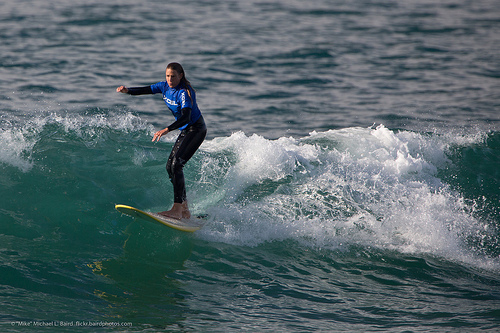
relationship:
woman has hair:
[109, 69, 225, 220] [126, 72, 225, 112]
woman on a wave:
[109, 69, 225, 220] [4, 112, 483, 236]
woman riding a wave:
[109, 69, 225, 220] [4, 112, 483, 236]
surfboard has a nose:
[90, 192, 246, 239] [108, 195, 156, 214]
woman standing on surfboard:
[109, 69, 225, 220] [90, 192, 246, 239]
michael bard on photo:
[28, 318, 115, 331] [33, 10, 475, 319]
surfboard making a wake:
[90, 192, 246, 239] [190, 172, 388, 264]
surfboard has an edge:
[90, 192, 246, 239] [148, 219, 203, 235]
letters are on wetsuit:
[153, 93, 188, 104] [126, 82, 228, 212]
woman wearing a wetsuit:
[109, 69, 225, 220] [126, 82, 228, 212]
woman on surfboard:
[109, 69, 225, 220] [90, 192, 246, 239]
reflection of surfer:
[82, 217, 194, 328] [117, 61, 206, 218]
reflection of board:
[82, 217, 194, 328] [114, 203, 212, 233]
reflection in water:
[82, 217, 194, 328] [4, 2, 492, 328]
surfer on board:
[117, 61, 206, 218] [114, 203, 212, 233]